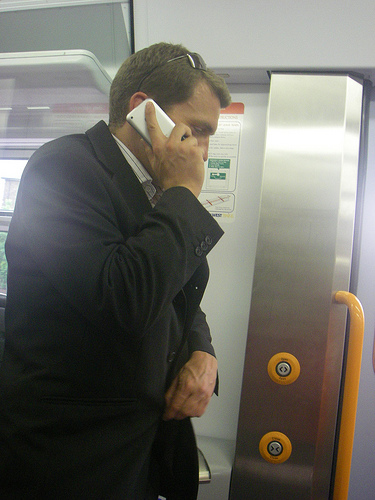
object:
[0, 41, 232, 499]
man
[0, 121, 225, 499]
jacket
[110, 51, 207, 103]
sunglasses